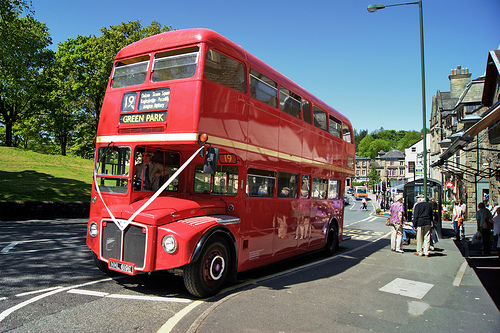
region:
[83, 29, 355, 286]
double decker red bus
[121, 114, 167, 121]
yellow and black green park sign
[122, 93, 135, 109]
black and white 19 sign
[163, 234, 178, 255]
circle bus headlight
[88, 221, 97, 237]
circle bus headlight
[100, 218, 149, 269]
square bus grate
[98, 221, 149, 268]
black and white license plate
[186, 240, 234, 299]
large bus wheel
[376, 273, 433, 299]
grey square on concrete street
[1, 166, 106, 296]
shadow of a large tree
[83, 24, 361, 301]
red bus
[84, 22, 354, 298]
red bus has large tires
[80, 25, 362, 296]
bus' headsign reads green park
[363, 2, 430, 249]
green street lamp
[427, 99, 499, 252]
scaffolding to right of bus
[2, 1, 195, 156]
trees to left of bus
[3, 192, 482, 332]
pavement markings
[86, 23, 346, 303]
bus has two floors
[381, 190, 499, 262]
people standing to right of bus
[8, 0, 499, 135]
sky is clear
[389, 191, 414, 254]
lady in pink on sidewalk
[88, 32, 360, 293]
red double decker bus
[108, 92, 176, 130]
next bus stop of bus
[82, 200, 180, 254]
headlights on the bus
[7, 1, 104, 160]
trees to the right of bus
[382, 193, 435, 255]
Man and lady talking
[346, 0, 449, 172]
street light along the street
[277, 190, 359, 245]
reflection of people on bus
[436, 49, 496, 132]
castle top of building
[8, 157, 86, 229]
shadow of tree in grass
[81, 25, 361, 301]
DOUBLE DECKER RED BUS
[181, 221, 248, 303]
BLACK BUS WHEEL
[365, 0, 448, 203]
TALL STREET LIGHT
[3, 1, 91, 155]
TREES IN THE DISTANCE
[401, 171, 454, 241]
BUS STOP SHELTER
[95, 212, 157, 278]
BUS GRILL IN FRONT OF BUS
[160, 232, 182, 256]
BUS HEADLIGHT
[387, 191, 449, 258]
TWO PEOPLE STANDING NEAR A STREET LIGHT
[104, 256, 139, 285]
BUS LICENSE PLATE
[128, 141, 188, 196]
MAN STANDING IN THE BUS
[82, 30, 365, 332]
a red stair cased bus on the road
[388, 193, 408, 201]
a man standing with a white cap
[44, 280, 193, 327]
a road marked with white color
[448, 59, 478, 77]
a chimney on top of the building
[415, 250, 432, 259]
a man with brown shoes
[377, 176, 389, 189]
a traffic light with red sign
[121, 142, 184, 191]
a driver on the bus sited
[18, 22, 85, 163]
tall trees beside the road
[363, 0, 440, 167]
a traffic light beside the road